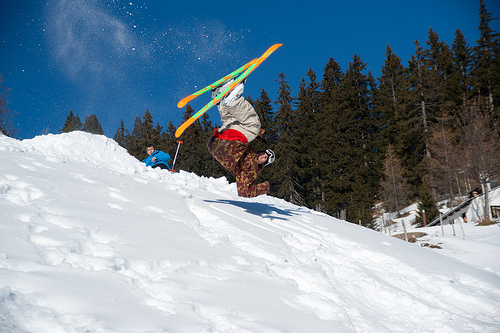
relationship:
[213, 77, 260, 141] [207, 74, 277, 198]
pants of man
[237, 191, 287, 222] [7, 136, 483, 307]
shadow on snow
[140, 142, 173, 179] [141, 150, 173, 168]
man wearing jacket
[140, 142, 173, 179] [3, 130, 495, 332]
man lying in snow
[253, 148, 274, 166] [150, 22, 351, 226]
head of a man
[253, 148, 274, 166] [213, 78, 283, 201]
head of a man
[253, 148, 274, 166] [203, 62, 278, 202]
head of a man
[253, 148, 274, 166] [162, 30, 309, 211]
head of a man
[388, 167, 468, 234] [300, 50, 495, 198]
house near trees